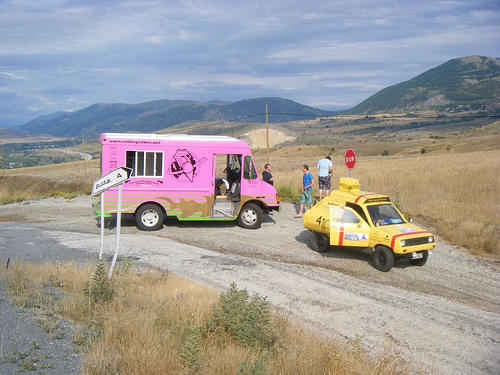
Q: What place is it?
A: It is a road.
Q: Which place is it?
A: It is a road.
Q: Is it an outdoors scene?
A: Yes, it is outdoors.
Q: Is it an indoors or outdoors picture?
A: It is outdoors.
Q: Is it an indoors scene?
A: No, it is outdoors.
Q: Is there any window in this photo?
A: Yes, there is a window.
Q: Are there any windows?
A: Yes, there is a window.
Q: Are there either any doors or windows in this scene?
A: Yes, there is a window.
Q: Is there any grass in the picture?
A: Yes, there is grass.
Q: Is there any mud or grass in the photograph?
A: Yes, there is grass.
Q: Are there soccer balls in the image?
A: No, there are no soccer balls.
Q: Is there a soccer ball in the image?
A: No, there are no soccer balls.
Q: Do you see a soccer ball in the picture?
A: No, there are no soccer balls.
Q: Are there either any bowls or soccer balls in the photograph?
A: No, there are no soccer balls or bowls.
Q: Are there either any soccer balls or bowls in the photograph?
A: No, there are no soccer balls or bowls.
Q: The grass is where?
A: The grass is in the field.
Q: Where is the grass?
A: The grass is in the field.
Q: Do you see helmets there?
A: No, there are no helmets.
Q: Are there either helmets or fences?
A: No, there are no helmets or fences.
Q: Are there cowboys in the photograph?
A: No, there are no cowboys.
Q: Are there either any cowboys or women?
A: No, there are no cowboys or women.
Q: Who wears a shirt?
A: The man wears a shirt.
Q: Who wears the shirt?
A: The man wears a shirt.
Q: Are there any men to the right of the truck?
A: Yes, there is a man to the right of the truck.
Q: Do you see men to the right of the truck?
A: Yes, there is a man to the right of the truck.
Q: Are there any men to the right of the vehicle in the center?
A: Yes, there is a man to the right of the truck.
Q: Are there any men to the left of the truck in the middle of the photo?
A: No, the man is to the right of the truck.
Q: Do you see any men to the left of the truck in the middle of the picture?
A: No, the man is to the right of the truck.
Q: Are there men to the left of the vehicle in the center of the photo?
A: No, the man is to the right of the truck.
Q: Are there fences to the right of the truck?
A: No, there is a man to the right of the truck.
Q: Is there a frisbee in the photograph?
A: No, there are no frisbees.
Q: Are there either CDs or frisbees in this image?
A: No, there are no frisbees or cds.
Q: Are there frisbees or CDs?
A: No, there are no frisbees or cds.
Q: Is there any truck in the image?
A: Yes, there is a truck.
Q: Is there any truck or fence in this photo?
A: Yes, there is a truck.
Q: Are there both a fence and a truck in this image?
A: No, there is a truck but no fences.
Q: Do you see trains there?
A: No, there are no trains.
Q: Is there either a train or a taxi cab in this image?
A: No, there are no trains or taxis.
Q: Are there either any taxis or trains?
A: No, there are no trains or taxis.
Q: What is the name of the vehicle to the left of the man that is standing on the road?
A: The vehicle is a truck.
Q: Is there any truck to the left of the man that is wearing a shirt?
A: Yes, there is a truck to the left of the man.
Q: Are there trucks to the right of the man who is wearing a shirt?
A: No, the truck is to the left of the man.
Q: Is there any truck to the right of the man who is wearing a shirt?
A: No, the truck is to the left of the man.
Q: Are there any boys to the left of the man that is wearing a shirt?
A: No, there is a truck to the left of the man.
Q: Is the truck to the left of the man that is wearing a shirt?
A: Yes, the truck is to the left of the man.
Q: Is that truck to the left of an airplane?
A: No, the truck is to the left of the man.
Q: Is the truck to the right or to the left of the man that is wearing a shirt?
A: The truck is to the left of the man.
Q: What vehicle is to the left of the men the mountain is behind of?
A: The vehicle is a truck.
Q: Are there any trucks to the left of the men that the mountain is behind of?
A: Yes, there is a truck to the left of the men.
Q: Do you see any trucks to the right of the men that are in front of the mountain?
A: No, the truck is to the left of the men.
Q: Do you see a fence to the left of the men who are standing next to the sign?
A: No, there is a truck to the left of the men.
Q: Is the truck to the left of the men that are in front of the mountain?
A: Yes, the truck is to the left of the men.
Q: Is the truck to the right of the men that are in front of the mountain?
A: No, the truck is to the left of the men.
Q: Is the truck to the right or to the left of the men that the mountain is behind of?
A: The truck is to the left of the men.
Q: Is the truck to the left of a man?
A: Yes, the truck is to the left of a man.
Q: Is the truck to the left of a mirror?
A: No, the truck is to the left of a man.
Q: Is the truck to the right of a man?
A: No, the truck is to the left of a man.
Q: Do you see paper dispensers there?
A: No, there are no paper dispensers.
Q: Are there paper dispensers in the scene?
A: No, there are no paper dispensers.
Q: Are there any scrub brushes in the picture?
A: No, there are no scrub brushes.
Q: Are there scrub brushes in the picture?
A: No, there are no scrub brushes.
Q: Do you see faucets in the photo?
A: No, there are no faucets.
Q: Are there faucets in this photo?
A: No, there are no faucets.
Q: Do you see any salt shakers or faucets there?
A: No, there are no faucets or salt shakers.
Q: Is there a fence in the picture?
A: No, there are no fences.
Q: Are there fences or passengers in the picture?
A: No, there are no fences or passengers.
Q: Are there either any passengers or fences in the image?
A: No, there are no fences or passengers.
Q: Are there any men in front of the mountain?
A: Yes, there are men in front of the mountain.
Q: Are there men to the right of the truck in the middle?
A: Yes, there are men to the right of the truck.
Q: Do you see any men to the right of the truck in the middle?
A: Yes, there are men to the right of the truck.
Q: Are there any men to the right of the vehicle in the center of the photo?
A: Yes, there are men to the right of the truck.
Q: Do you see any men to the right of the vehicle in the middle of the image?
A: Yes, there are men to the right of the truck.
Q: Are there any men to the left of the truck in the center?
A: No, the men are to the right of the truck.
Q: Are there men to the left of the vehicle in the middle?
A: No, the men are to the right of the truck.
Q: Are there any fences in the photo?
A: No, there are no fences.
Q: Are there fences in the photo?
A: No, there are no fences.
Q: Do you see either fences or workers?
A: No, there are no fences or workers.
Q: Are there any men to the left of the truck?
A: No, the man is to the right of the truck.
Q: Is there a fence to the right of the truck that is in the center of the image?
A: No, there is a man to the right of the truck.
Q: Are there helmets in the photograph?
A: No, there are no helmets.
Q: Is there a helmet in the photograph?
A: No, there are no helmets.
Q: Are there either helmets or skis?
A: No, there are no helmets or skis.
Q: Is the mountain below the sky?
A: Yes, the mountain is below the sky.